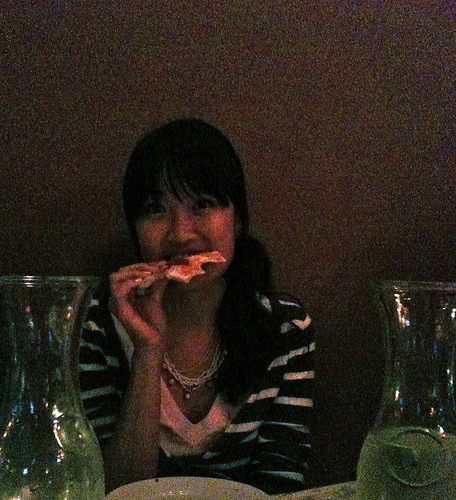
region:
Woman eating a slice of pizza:
[74, 115, 317, 489]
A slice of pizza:
[114, 245, 248, 284]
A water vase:
[356, 273, 455, 498]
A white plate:
[99, 474, 288, 498]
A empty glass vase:
[0, 273, 107, 498]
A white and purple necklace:
[148, 338, 230, 402]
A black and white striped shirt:
[73, 287, 316, 498]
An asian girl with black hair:
[77, 116, 316, 488]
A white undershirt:
[109, 310, 248, 458]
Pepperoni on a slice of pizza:
[165, 257, 192, 266]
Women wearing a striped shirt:
[81, 160, 320, 492]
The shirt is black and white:
[81, 276, 317, 483]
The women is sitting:
[74, 167, 326, 471]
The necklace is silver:
[146, 323, 226, 397]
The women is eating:
[78, 161, 315, 486]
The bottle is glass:
[334, 278, 448, 495]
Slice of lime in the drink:
[359, 423, 445, 482]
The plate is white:
[96, 456, 267, 495]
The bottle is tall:
[343, 274, 446, 496]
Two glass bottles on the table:
[9, 263, 454, 498]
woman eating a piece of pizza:
[70, 114, 318, 491]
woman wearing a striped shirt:
[70, 118, 311, 495]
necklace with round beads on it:
[150, 328, 238, 401]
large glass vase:
[0, 271, 114, 489]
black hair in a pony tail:
[116, 118, 273, 403]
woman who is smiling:
[106, 112, 270, 333]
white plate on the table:
[102, 466, 278, 497]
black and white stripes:
[221, 378, 319, 471]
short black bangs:
[129, 151, 233, 215]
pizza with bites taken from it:
[139, 247, 210, 288]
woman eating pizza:
[73, 107, 326, 484]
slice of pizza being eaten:
[136, 249, 222, 287]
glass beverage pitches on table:
[6, 260, 449, 499]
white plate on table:
[114, 470, 269, 498]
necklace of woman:
[145, 344, 229, 406]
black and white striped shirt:
[78, 277, 310, 491]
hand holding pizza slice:
[104, 254, 176, 348]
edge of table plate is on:
[277, 473, 356, 499]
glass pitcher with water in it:
[351, 271, 453, 499]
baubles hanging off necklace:
[156, 363, 227, 413]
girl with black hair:
[99, 114, 252, 254]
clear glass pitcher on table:
[1, 269, 110, 497]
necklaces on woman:
[162, 350, 227, 398]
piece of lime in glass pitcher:
[374, 406, 451, 491]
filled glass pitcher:
[349, 265, 454, 498]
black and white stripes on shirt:
[253, 385, 315, 473]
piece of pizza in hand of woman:
[102, 232, 242, 319]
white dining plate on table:
[92, 471, 281, 497]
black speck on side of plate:
[150, 467, 174, 486]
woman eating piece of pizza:
[55, 105, 320, 458]